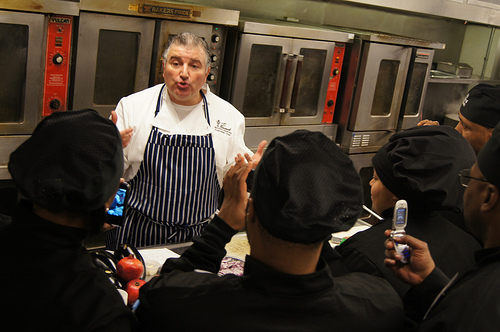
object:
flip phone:
[390, 199, 412, 264]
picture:
[394, 206, 406, 226]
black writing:
[214, 117, 233, 137]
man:
[0, 108, 145, 332]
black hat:
[249, 129, 365, 248]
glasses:
[456, 168, 500, 190]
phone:
[105, 182, 131, 227]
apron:
[100, 83, 222, 256]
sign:
[139, 4, 190, 18]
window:
[93, 29, 142, 108]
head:
[160, 30, 213, 102]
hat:
[6, 107, 124, 215]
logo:
[213, 119, 233, 136]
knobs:
[326, 99, 334, 108]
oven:
[219, 12, 357, 156]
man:
[381, 124, 500, 332]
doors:
[227, 34, 292, 127]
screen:
[102, 185, 128, 216]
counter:
[79, 217, 380, 311]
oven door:
[0, 10, 46, 136]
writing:
[459, 92, 469, 108]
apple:
[116, 253, 145, 281]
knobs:
[46, 96, 62, 111]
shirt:
[0, 199, 139, 332]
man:
[105, 29, 270, 253]